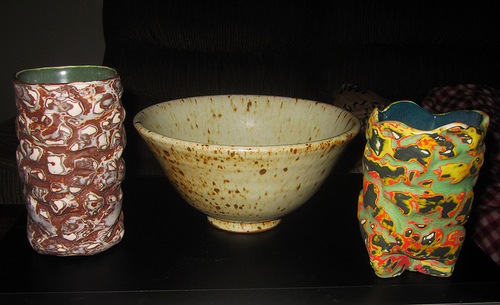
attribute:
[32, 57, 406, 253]
pots — behind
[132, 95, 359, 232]
bowl —  middle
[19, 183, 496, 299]
table — black 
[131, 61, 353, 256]
bowl — interior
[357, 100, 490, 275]
pot — decorative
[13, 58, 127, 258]
pot — reddish